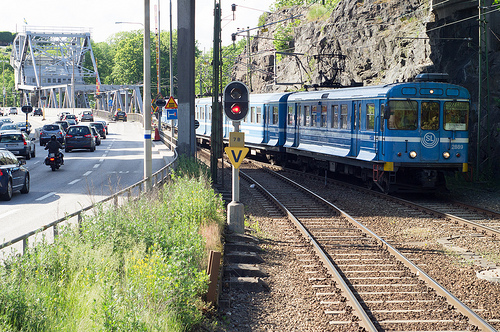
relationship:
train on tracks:
[154, 87, 468, 192] [334, 172, 500, 240]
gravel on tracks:
[207, 138, 493, 331] [334, 172, 500, 240]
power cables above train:
[213, 0, 495, 88] [154, 87, 468, 192]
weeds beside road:
[3, 164, 227, 331] [3, 102, 169, 267]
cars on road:
[1, 96, 129, 203] [3, 102, 169, 267]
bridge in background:
[7, 27, 152, 116] [0, 6, 500, 115]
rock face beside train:
[233, 2, 494, 85] [154, 87, 468, 192]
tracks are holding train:
[334, 172, 500, 240] [154, 87, 468, 192]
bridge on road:
[7, 27, 152, 116] [3, 102, 169, 267]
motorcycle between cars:
[38, 134, 66, 174] [0, 124, 99, 198]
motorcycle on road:
[38, 134, 66, 174] [3, 102, 169, 267]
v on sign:
[230, 147, 246, 165] [221, 144, 251, 170]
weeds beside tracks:
[3, 164, 227, 331] [334, 172, 500, 240]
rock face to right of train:
[233, 2, 494, 85] [154, 87, 468, 192]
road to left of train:
[3, 102, 169, 267] [154, 87, 468, 192]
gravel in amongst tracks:
[207, 138, 493, 331] [334, 172, 500, 240]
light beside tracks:
[230, 103, 243, 116] [334, 172, 500, 240]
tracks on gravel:
[334, 172, 500, 240] [207, 138, 493, 331]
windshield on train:
[388, 98, 469, 130] [154, 87, 468, 192]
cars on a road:
[1, 96, 129, 203] [3, 102, 169, 267]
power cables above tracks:
[213, 0, 495, 88] [334, 172, 500, 240]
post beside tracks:
[203, 247, 230, 312] [334, 172, 500, 240]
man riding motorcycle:
[45, 136, 61, 154] [38, 134, 66, 174]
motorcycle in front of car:
[38, 134, 66, 174] [1, 151, 29, 195]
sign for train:
[221, 144, 251, 170] [154, 87, 468, 192]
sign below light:
[221, 144, 251, 170] [230, 103, 243, 116]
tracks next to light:
[204, 147, 492, 332] [230, 103, 243, 116]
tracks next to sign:
[204, 147, 492, 332] [221, 144, 251, 170]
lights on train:
[407, 86, 452, 160] [154, 87, 468, 192]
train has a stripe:
[154, 87, 468, 192] [249, 124, 467, 149]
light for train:
[230, 103, 243, 116] [154, 87, 468, 192]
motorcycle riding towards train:
[38, 134, 66, 174] [154, 87, 468, 192]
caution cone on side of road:
[152, 127, 162, 145] [3, 102, 169, 267]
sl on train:
[427, 136, 439, 146] [154, 87, 468, 192]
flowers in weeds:
[42, 243, 209, 331] [3, 164, 227, 331]